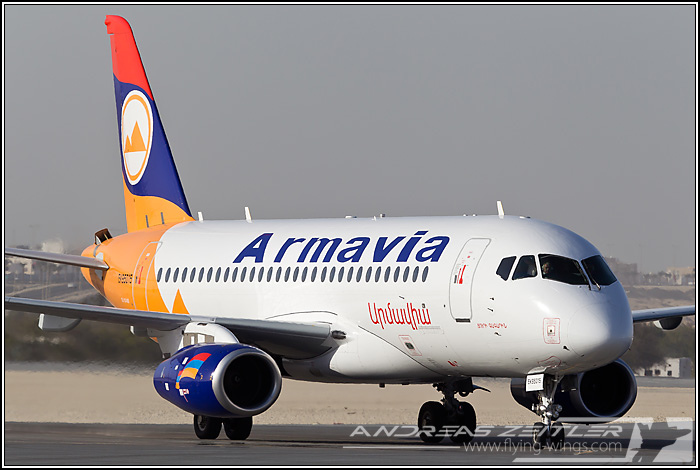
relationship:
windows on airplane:
[147, 268, 428, 282] [0, 13, 694, 440]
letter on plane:
[233, 230, 449, 264] [0, 15, 700, 451]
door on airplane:
[442, 234, 489, 323] [0, 13, 694, 440]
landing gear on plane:
[528, 390, 570, 449] [0, 15, 700, 451]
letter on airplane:
[233, 230, 449, 264] [0, 13, 694, 440]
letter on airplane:
[272, 236, 302, 262] [0, 13, 694, 440]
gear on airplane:
[408, 395, 486, 435] [0, 13, 694, 440]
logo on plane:
[75, 87, 184, 191] [68, 115, 673, 465]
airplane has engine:
[0, 13, 694, 440] [143, 336, 294, 426]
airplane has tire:
[0, 13, 694, 440] [410, 397, 485, 444]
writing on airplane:
[362, 292, 434, 335] [0, 13, 694, 440]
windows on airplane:
[153, 260, 431, 286] [0, 13, 694, 440]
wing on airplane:
[9, 287, 339, 357] [0, 13, 694, 440]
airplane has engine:
[0, 13, 694, 440] [148, 333, 295, 419]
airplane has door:
[0, 13, 694, 440] [442, 234, 489, 323]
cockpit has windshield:
[485, 201, 641, 372] [495, 252, 615, 290]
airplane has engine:
[0, 13, 694, 440] [499, 360, 654, 427]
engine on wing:
[143, 336, 294, 426] [8, 287, 340, 348]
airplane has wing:
[0, 13, 694, 440] [9, 287, 339, 357]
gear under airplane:
[408, 395, 486, 435] [0, 13, 694, 440]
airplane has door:
[0, 13, 694, 440] [114, 233, 145, 304]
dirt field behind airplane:
[8, 369, 699, 427] [0, 13, 694, 440]